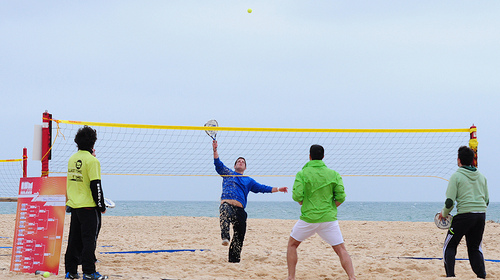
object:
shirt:
[216, 159, 274, 206]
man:
[61, 126, 111, 279]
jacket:
[291, 160, 348, 221]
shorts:
[291, 219, 349, 246]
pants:
[441, 209, 485, 275]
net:
[51, 115, 469, 181]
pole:
[42, 112, 54, 175]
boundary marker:
[114, 241, 215, 262]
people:
[207, 138, 291, 261]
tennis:
[8, 24, 499, 269]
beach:
[136, 224, 172, 244]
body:
[140, 201, 166, 209]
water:
[127, 200, 156, 217]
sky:
[213, 23, 313, 53]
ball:
[246, 8, 255, 14]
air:
[192, 26, 218, 36]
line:
[388, 248, 442, 267]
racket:
[202, 117, 223, 141]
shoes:
[85, 272, 103, 279]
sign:
[9, 176, 68, 275]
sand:
[363, 226, 402, 248]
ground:
[167, 263, 225, 274]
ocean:
[147, 202, 184, 214]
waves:
[364, 205, 394, 216]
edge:
[460, 126, 471, 136]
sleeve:
[88, 163, 106, 203]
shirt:
[67, 150, 106, 207]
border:
[375, 219, 400, 222]